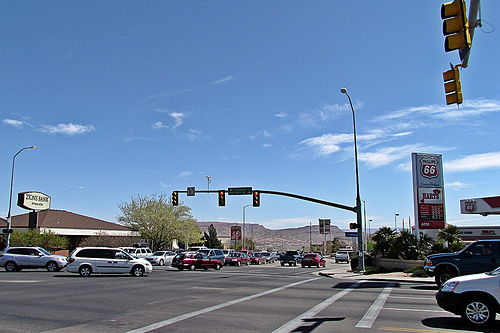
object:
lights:
[252, 189, 261, 207]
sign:
[17, 191, 52, 211]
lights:
[218, 189, 226, 207]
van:
[65, 246, 153, 276]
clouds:
[150, 102, 394, 169]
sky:
[14, 4, 255, 50]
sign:
[318, 218, 332, 235]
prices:
[417, 186, 445, 227]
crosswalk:
[355, 280, 447, 332]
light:
[171, 191, 179, 206]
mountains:
[197, 221, 345, 252]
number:
[422, 165, 437, 174]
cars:
[434, 265, 499, 326]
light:
[442, 61, 463, 106]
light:
[440, 0, 472, 61]